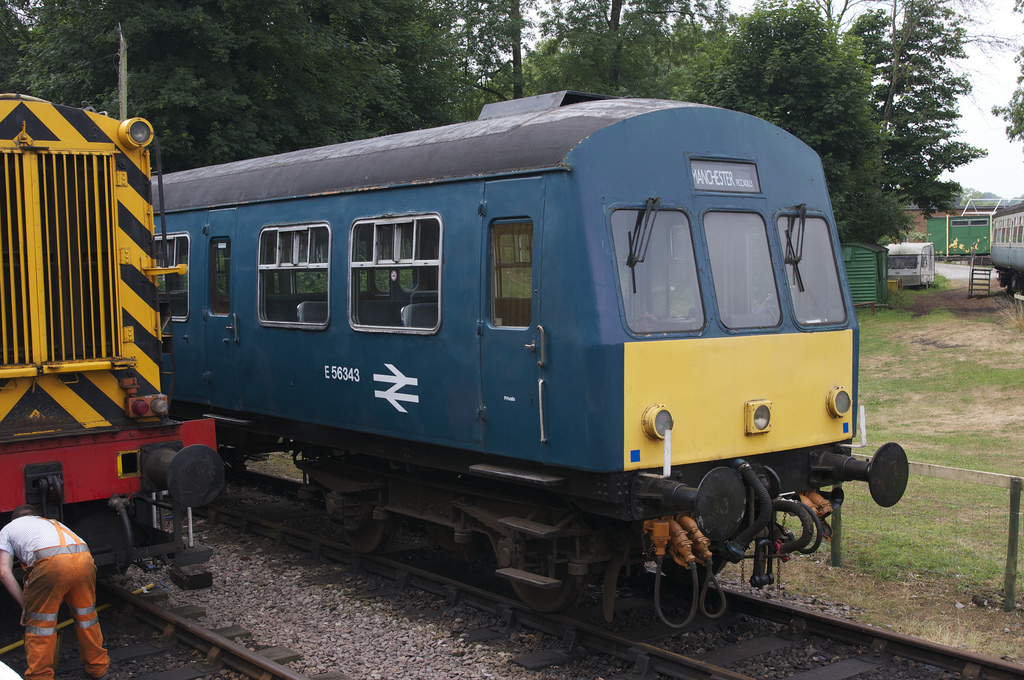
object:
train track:
[0, 435, 1024, 680]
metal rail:
[707, 586, 1024, 680]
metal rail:
[107, 462, 1024, 679]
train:
[0, 90, 219, 529]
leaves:
[733, 51, 837, 107]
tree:
[701, 0, 901, 267]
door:
[476, 176, 550, 463]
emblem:
[373, 363, 420, 413]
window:
[348, 218, 443, 332]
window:
[257, 220, 329, 326]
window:
[156, 230, 189, 322]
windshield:
[610, 208, 851, 339]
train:
[154, 88, 909, 631]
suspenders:
[38, 517, 84, 547]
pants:
[24, 549, 112, 680]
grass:
[777, 274, 1024, 602]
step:
[495, 568, 561, 589]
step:
[496, 516, 562, 540]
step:
[469, 463, 567, 486]